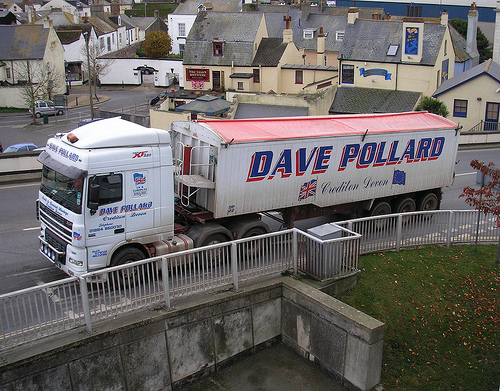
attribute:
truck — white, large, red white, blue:
[37, 112, 462, 284]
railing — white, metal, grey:
[2, 209, 499, 363]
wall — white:
[0, 269, 384, 390]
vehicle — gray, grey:
[28, 98, 68, 119]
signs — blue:
[357, 19, 421, 80]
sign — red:
[183, 67, 211, 83]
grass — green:
[330, 242, 499, 389]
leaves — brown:
[419, 259, 498, 340]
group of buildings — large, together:
[1, 0, 498, 135]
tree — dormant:
[79, 35, 110, 119]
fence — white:
[0, 207, 497, 360]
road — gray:
[3, 148, 498, 338]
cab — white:
[35, 114, 176, 286]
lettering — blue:
[98, 200, 154, 216]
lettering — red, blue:
[245, 137, 446, 180]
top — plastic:
[194, 110, 457, 145]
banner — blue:
[356, 67, 393, 82]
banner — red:
[184, 64, 210, 83]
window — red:
[211, 40, 223, 58]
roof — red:
[176, 109, 463, 146]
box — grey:
[307, 222, 345, 279]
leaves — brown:
[460, 158, 499, 229]